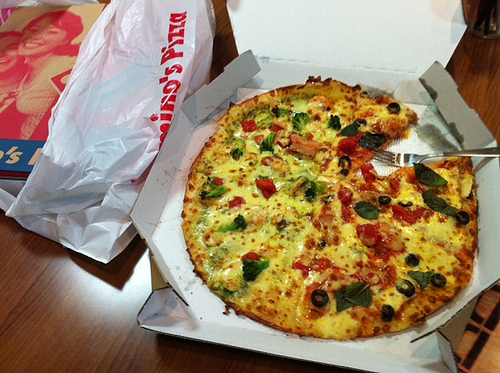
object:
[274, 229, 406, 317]
toppings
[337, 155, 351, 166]
olive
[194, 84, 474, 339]
cheese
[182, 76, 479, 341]
pie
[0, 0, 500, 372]
table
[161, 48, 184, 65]
letters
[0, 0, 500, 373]
shop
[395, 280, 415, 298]
olive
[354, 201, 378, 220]
spinach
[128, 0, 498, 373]
box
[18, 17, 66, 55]
face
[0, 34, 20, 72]
face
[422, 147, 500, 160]
handle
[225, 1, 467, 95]
top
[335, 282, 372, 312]
leaves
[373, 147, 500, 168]
fork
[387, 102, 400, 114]
olives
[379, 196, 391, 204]
olives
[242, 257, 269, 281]
broccoli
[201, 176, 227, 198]
broccoli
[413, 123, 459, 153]
stain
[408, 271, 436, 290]
spinach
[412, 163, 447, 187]
spinach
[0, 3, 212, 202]
box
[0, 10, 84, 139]
woman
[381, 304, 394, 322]
olive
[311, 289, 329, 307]
olive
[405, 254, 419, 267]
olive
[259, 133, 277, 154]
broccoli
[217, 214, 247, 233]
broccoli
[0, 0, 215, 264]
bag